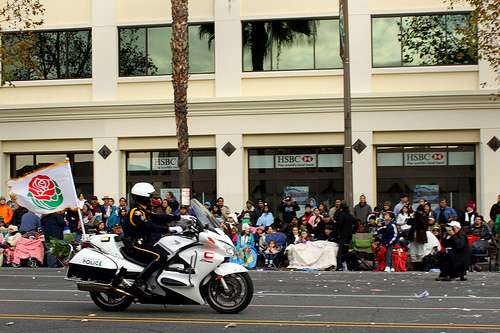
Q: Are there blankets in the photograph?
A: Yes, there is a blanket.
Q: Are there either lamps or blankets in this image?
A: Yes, there is a blanket.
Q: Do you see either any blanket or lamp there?
A: Yes, there is a blanket.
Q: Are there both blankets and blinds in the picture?
A: No, there is a blanket but no blinds.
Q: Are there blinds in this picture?
A: No, there are no blinds.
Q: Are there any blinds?
A: No, there are no blinds.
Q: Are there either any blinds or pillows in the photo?
A: No, there are no blinds or pillows.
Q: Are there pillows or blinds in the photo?
A: No, there are no blinds or pillows.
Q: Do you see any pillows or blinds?
A: No, there are no blinds or pillows.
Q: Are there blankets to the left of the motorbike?
A: Yes, there is a blanket to the left of the motorbike.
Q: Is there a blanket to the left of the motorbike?
A: Yes, there is a blanket to the left of the motorbike.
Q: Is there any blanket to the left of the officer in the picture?
A: Yes, there is a blanket to the left of the officer.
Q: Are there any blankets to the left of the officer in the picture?
A: Yes, there is a blanket to the left of the officer.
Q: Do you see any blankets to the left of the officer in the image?
A: Yes, there is a blanket to the left of the officer.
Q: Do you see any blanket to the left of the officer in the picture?
A: Yes, there is a blanket to the left of the officer.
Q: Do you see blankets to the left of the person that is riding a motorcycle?
A: Yes, there is a blanket to the left of the officer.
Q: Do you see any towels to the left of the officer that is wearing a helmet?
A: No, there is a blanket to the left of the officer.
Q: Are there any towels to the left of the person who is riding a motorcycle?
A: No, there is a blanket to the left of the officer.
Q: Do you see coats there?
A: Yes, there is a coat.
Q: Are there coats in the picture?
A: Yes, there is a coat.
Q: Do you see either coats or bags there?
A: Yes, there is a coat.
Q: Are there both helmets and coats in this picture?
A: Yes, there are both a coat and a helmet.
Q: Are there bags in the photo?
A: No, there are no bags.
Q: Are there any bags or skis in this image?
A: No, there are no bags or skis.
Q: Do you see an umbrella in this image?
A: No, there are no umbrellas.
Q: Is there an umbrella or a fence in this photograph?
A: No, there are no umbrellas or fences.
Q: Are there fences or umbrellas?
A: No, there are no umbrellas or fences.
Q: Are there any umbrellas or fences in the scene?
A: No, there are no umbrellas or fences.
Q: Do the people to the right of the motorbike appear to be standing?
A: Yes, the people are standing.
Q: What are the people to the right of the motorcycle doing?
A: The people are standing.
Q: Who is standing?
A: The people are standing.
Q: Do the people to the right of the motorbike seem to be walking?
A: No, the people are standing.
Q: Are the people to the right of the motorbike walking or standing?
A: The people are standing.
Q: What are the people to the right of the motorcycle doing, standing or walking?
A: The people are standing.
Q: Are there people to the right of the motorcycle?
A: Yes, there are people to the right of the motorcycle.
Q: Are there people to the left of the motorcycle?
A: No, the people are to the right of the motorcycle.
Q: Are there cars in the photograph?
A: No, there are no cars.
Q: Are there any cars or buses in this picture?
A: No, there are no cars or buses.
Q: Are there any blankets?
A: Yes, there is a blanket.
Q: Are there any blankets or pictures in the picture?
A: Yes, there is a blanket.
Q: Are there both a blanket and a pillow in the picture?
A: No, there is a blanket but no pillows.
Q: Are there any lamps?
A: No, there are no lamps.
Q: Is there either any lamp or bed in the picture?
A: No, there are no lamps or beds.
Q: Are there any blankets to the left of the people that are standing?
A: Yes, there is a blanket to the left of the people.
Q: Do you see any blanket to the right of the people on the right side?
A: No, the blanket is to the left of the people.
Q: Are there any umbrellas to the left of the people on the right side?
A: No, there is a blanket to the left of the people.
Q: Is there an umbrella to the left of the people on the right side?
A: No, there is a blanket to the left of the people.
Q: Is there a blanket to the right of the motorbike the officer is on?
A: Yes, there is a blanket to the right of the motorbike.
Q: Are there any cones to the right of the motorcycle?
A: No, there is a blanket to the right of the motorcycle.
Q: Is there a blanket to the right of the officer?
A: Yes, there is a blanket to the right of the officer.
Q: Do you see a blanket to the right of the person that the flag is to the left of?
A: Yes, there is a blanket to the right of the officer.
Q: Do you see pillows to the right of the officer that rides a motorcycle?
A: No, there is a blanket to the right of the officer.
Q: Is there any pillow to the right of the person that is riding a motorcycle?
A: No, there is a blanket to the right of the officer.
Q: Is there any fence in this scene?
A: No, there are no fences.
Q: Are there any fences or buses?
A: No, there are no fences or buses.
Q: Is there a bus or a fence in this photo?
A: No, there are no fences or buses.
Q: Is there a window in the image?
A: Yes, there is a window.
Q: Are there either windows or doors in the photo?
A: Yes, there is a window.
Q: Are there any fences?
A: No, there are no fences.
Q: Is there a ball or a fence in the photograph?
A: No, there are no fences or balls.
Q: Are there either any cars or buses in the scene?
A: No, there are no cars or buses.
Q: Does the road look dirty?
A: Yes, the road is dirty.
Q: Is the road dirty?
A: Yes, the road is dirty.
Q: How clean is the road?
A: The road is dirty.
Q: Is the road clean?
A: No, the road is dirty.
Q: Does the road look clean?
A: No, the road is dirty.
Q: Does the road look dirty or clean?
A: The road is dirty.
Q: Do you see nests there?
A: No, there are no nests.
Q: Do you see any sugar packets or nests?
A: No, there are no nests or sugar packets.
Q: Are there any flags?
A: Yes, there is a flag.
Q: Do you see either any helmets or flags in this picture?
A: Yes, there is a flag.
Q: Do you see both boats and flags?
A: No, there is a flag but no boats.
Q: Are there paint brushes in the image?
A: No, there are no paint brushes.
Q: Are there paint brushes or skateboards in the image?
A: No, there are no paint brushes or skateboards.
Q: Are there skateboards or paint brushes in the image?
A: No, there are no paint brushes or skateboards.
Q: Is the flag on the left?
A: Yes, the flag is on the left of the image.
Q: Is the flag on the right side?
A: No, the flag is on the left of the image.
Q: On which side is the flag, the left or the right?
A: The flag is on the left of the image.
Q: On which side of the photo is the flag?
A: The flag is on the left of the image.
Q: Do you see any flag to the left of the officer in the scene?
A: Yes, there is a flag to the left of the officer.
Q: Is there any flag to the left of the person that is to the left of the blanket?
A: Yes, there is a flag to the left of the officer.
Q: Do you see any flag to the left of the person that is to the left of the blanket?
A: Yes, there is a flag to the left of the officer.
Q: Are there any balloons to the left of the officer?
A: No, there is a flag to the left of the officer.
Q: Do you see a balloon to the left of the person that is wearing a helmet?
A: No, there is a flag to the left of the officer.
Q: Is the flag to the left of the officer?
A: Yes, the flag is to the left of the officer.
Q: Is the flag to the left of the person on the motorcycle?
A: Yes, the flag is to the left of the officer.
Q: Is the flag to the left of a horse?
A: No, the flag is to the left of the officer.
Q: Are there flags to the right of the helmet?
A: No, the flag is to the left of the helmet.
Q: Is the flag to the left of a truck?
A: No, the flag is to the left of the helmet.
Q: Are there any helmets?
A: Yes, there is a helmet.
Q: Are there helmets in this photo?
A: Yes, there is a helmet.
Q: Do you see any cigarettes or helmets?
A: Yes, there is a helmet.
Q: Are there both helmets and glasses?
A: No, there is a helmet but no glasses.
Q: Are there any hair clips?
A: No, there are no hair clips.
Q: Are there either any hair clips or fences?
A: No, there are no hair clips or fences.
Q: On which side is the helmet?
A: The helmet is on the left of the image.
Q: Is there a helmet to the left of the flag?
A: No, the helmet is to the right of the flag.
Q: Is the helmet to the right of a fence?
A: No, the helmet is to the right of a flag.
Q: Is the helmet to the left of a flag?
A: No, the helmet is to the right of a flag.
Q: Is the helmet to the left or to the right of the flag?
A: The helmet is to the right of the flag.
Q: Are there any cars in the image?
A: No, there are no cars.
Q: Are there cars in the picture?
A: No, there are no cars.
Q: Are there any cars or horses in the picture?
A: No, there are no cars or horses.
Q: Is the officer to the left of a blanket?
A: Yes, the officer is to the left of a blanket.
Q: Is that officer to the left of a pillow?
A: No, the officer is to the left of a blanket.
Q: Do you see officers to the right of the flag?
A: Yes, there is an officer to the right of the flag.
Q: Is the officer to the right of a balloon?
A: No, the officer is to the right of the flag.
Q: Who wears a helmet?
A: The officer wears a helmet.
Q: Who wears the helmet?
A: The officer wears a helmet.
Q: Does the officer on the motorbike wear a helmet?
A: Yes, the officer wears a helmet.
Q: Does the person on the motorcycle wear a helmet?
A: Yes, the officer wears a helmet.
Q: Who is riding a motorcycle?
A: The officer is riding a motorcycle.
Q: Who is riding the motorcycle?
A: The officer is riding a motorcycle.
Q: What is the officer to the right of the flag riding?
A: The officer is riding a motorcycle.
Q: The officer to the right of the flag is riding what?
A: The officer is riding a motorcycle.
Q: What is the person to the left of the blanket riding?
A: The officer is riding a motorcycle.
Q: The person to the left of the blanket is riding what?
A: The officer is riding a motorcycle.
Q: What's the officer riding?
A: The officer is riding a motorcycle.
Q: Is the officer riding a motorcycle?
A: Yes, the officer is riding a motorcycle.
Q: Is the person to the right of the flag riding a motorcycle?
A: Yes, the officer is riding a motorcycle.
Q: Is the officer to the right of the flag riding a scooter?
A: No, the officer is riding a motorcycle.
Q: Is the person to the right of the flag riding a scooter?
A: No, the officer is riding a motorcycle.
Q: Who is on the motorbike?
A: The officer is on the motorbike.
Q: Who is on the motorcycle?
A: The officer is on the motorbike.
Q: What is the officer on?
A: The officer is on the motorcycle.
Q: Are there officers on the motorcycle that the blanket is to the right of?
A: Yes, there is an officer on the motorcycle.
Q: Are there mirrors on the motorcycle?
A: No, there is an officer on the motorcycle.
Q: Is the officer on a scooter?
A: No, the officer is on the motorbike.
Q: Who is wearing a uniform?
A: The officer is wearing a uniform.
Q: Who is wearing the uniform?
A: The officer is wearing a uniform.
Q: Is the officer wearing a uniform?
A: Yes, the officer is wearing a uniform.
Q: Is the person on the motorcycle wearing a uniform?
A: Yes, the officer is wearing a uniform.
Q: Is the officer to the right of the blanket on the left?
A: Yes, the officer is to the right of the blanket.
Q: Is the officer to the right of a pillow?
A: No, the officer is to the right of the blanket.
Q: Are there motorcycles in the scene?
A: Yes, there is a motorcycle.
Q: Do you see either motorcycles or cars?
A: Yes, there is a motorcycle.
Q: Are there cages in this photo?
A: No, there are no cages.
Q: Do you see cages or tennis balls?
A: No, there are no cages or tennis balls.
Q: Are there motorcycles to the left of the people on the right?
A: Yes, there is a motorcycle to the left of the people.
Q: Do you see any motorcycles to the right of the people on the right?
A: No, the motorcycle is to the left of the people.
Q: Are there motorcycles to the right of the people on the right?
A: No, the motorcycle is to the left of the people.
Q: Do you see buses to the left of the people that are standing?
A: No, there is a motorcycle to the left of the people.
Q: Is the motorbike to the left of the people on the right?
A: Yes, the motorbike is to the left of the people.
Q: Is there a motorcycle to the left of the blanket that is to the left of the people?
A: Yes, there is a motorcycle to the left of the blanket.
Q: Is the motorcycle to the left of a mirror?
A: No, the motorcycle is to the left of a blanket.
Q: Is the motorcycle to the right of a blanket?
A: Yes, the motorcycle is to the right of a blanket.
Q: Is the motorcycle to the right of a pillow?
A: No, the motorcycle is to the right of a blanket.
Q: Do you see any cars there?
A: No, there are no cars.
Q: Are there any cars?
A: No, there are no cars.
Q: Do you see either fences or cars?
A: No, there are no cars or fences.